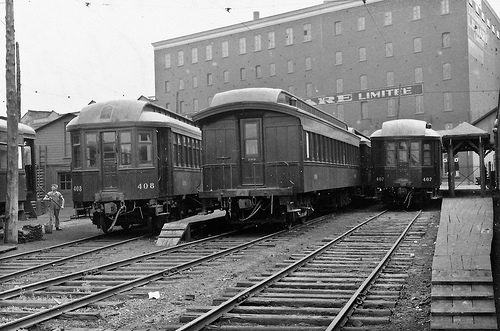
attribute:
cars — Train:
[87, 77, 452, 214]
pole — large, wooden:
[3, 7, 32, 257]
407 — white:
[419, 173, 438, 186]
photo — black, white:
[1, 0, 498, 327]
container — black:
[189, 85, 369, 226]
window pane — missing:
[298, 26, 310, 42]